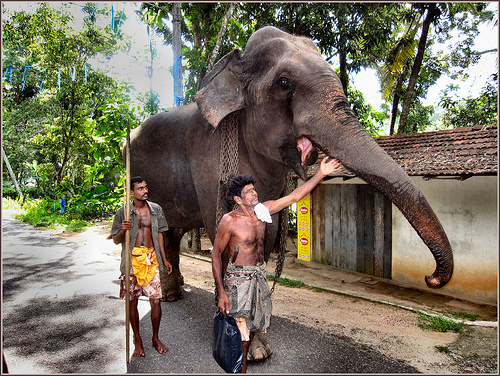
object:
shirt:
[246, 200, 274, 221]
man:
[205, 155, 345, 375]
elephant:
[112, 18, 456, 303]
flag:
[55, 190, 73, 217]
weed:
[40, 193, 91, 236]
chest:
[233, 220, 264, 254]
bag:
[210, 305, 243, 372]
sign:
[298, 206, 316, 240]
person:
[102, 172, 172, 362]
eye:
[276, 69, 299, 92]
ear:
[191, 63, 247, 130]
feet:
[124, 338, 151, 358]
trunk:
[307, 107, 462, 288]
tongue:
[292, 132, 313, 158]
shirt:
[150, 191, 175, 242]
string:
[206, 306, 245, 325]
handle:
[111, 153, 144, 200]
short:
[225, 261, 284, 332]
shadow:
[32, 297, 71, 336]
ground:
[27, 246, 111, 365]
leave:
[47, 60, 80, 95]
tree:
[0, 57, 102, 205]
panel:
[335, 184, 384, 265]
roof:
[413, 140, 457, 159]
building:
[246, 114, 488, 297]